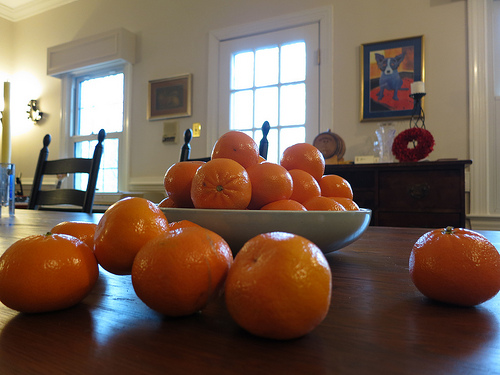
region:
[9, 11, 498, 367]
A dining room scene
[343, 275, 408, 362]
A wooden table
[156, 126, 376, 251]
A bowl of oranges is on the table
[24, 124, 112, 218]
A chair is near the table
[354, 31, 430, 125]
A framed painting is on the wall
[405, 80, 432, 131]
A candle stick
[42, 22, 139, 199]
A window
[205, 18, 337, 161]
This is a door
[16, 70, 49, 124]
A light is hanging on the wall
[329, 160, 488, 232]
A chest of drawers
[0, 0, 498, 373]
Oranges placed on a table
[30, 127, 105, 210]
A brown chair next to a table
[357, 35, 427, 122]
A wall painting of a dog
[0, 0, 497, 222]
A white painted room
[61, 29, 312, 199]
Two fully lightened windows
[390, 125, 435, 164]
A red rounded artwork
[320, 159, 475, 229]
A brown colored cabinet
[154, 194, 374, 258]
White bowl full of oranges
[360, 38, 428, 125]
A wall lighting next to a painting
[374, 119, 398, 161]
A glassware on top the cabinet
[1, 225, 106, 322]
small bright orange nectarine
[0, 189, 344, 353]
bunch of small oranges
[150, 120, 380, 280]
large bowl of oranges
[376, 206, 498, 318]
single orange a table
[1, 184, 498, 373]
large wooden dining table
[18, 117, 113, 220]
single wooden dining chair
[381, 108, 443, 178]
red flower wreath decoration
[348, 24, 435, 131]
small wall picture of dog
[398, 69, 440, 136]
tall black metal candelabra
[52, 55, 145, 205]
large bright dining room window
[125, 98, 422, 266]
a bowl of oranges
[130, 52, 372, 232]
a pile of oranges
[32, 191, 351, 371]
oranges on the table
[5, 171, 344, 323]
oranges on the brown table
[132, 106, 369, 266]
a pile of oranges in a bowl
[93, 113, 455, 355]
oranges on a brown table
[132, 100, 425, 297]
bowl of oranges on table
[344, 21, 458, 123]
a picture on the wall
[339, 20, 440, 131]
a framed picture on the wall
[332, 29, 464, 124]
a picture framed in gold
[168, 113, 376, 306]
a bowl of oranges on table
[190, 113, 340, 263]
a bowl on the table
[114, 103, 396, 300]
a bowl on a brown table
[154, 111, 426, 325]
a bowl of oranges on brown table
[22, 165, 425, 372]
oranges on tables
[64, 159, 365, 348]
oranges on brown table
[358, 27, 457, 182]
a painting of a dog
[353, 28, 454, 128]
a framed painting of a dog